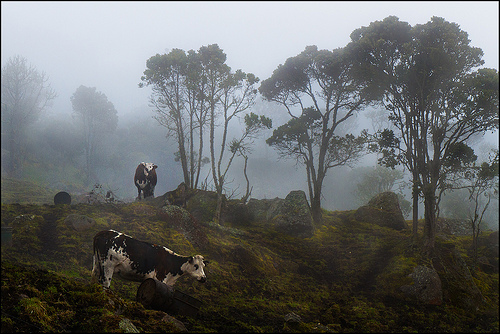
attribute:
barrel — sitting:
[136, 276, 182, 310]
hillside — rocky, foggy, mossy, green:
[24, 198, 498, 332]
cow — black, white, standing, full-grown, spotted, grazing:
[92, 231, 210, 294]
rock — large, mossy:
[267, 191, 309, 234]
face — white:
[191, 259, 208, 281]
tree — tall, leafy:
[263, 50, 373, 223]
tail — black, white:
[91, 243, 97, 275]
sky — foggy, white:
[1, 2, 498, 187]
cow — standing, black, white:
[134, 162, 161, 199]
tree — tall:
[146, 52, 210, 193]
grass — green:
[49, 205, 324, 320]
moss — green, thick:
[15, 274, 103, 325]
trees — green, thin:
[142, 22, 497, 214]